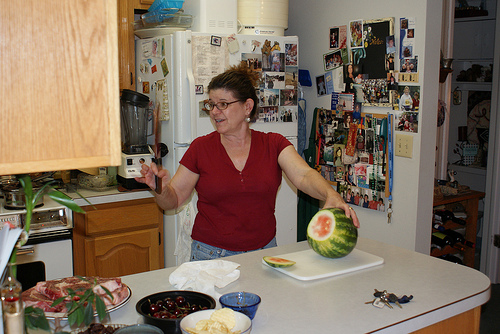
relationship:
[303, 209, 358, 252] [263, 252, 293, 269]
watermelon has rind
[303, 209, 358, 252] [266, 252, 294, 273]
watermelon has rind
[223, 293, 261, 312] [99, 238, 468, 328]
bowl on countertop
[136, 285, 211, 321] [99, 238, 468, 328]
bowl on countertop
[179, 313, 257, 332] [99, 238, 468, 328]
bowl on countertop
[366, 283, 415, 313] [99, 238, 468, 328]
keys on countertop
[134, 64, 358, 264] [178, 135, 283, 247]
woman wearing shirt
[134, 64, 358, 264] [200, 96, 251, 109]
woman wearing glasses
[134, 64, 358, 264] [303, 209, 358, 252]
woman holding watermelon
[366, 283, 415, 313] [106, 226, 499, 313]
key ring laying counter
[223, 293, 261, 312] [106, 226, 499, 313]
bowl on counter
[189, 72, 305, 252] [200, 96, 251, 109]
woman has eyeglasses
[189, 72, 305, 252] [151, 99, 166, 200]
woman holding knife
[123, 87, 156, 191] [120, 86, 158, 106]
blender has lid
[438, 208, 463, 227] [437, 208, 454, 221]
bottle of wine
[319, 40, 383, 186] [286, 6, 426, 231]
photographs on wall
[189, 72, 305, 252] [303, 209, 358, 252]
woman holding watermelon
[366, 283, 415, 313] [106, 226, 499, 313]
keys on counter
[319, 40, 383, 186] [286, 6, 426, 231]
pictures on wall